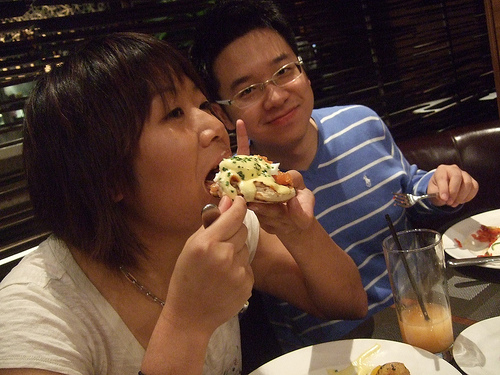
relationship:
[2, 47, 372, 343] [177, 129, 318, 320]
person with hands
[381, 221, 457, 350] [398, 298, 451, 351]
glass has juice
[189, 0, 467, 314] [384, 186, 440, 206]
man holding fork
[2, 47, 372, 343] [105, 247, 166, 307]
person wearing necklace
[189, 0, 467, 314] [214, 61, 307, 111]
man has glasses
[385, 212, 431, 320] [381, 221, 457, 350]
straw in glass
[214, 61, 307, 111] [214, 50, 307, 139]
glasses on face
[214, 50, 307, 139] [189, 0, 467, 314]
face of man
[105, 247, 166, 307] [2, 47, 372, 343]
necklace on person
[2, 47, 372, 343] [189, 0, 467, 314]
person with man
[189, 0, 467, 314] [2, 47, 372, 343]
man with person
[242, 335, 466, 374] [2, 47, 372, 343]
plate in front of person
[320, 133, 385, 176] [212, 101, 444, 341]
stripe in shirt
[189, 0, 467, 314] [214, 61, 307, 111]
man wearing glasses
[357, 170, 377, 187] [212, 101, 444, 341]
logo on shirt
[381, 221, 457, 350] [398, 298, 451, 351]
glass with juice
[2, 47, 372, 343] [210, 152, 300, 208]
person eating food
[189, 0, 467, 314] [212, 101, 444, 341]
man wearing shirt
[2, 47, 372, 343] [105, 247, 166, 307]
person wears necklace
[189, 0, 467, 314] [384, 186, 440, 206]
man holds fork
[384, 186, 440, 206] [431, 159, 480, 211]
fork in hands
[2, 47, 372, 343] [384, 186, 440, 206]
person holds fork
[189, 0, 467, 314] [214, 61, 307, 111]
man wears glasses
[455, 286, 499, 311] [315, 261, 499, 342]
reflection on table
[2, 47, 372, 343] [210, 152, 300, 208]
person bites food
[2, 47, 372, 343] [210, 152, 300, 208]
person holds food